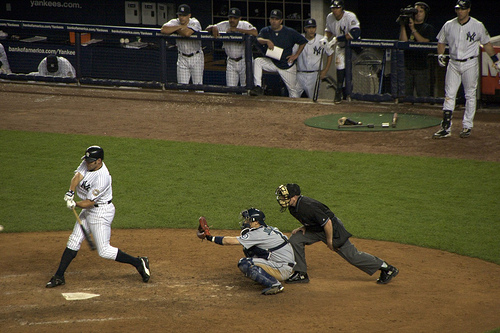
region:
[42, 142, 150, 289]
Baseball batter swinging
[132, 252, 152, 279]
Black and white shoe on baseball batter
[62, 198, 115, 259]
White pants with pinstripes on baseball batter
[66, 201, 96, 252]
Brown and black bat held by baseball batter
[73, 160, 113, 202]
White jersey with pinstripes on baseball batter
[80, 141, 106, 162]
Black helmet on baseball batter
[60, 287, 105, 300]
White home plate on a baseball field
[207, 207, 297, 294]
Catcher in squat in baseball game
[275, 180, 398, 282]
Home plate umpire in dark clothing in baseball game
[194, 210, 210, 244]
Brown mitt on baseball catcher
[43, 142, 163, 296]
Baseball batter swinging at a pitch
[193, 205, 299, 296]
Baseball catcher about to catch a pitch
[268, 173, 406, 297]
Baseball umpire alert and ready to make a call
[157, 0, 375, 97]
Baseball players in the dugout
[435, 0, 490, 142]
Baseball batter on deck about to hit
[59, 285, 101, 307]
Home plate of a baseball game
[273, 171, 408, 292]
Home plate umpire of a baseball game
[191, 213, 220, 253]
Baseball catching glove being worn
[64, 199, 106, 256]
Baseball bat mid swing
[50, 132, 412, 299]
Baseball hitter, catcher, and umpire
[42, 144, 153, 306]
Batter at home plate.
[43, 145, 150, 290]
Baseball player swinging a bat.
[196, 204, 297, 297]
Catcher crouching to catch the ball.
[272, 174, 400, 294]
Umpire dressed mainly in black.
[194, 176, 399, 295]
Catcher with umpire standing behind him.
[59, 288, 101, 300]
Home plate.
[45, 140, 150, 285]
Player up at bat.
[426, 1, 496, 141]
Player on deck.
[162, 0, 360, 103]
Team waiting in the dugout.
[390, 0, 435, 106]
Cameraman filming the game.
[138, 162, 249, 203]
green artificial turf on field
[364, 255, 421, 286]
black top sneakers with white spot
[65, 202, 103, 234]
wooden bat in player's hand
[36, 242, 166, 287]
pair of tall black socks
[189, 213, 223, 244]
brown glove in catcher's hand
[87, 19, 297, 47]
black railing in the bull pen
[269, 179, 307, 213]
brown and gold face mask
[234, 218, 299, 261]
strap around catcher's waist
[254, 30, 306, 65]
white paper in man's hand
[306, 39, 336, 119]
shiny black baseball bat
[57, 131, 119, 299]
base ball player wearing uniform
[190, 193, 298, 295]
base ball player wearing uniform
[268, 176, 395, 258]
base ball player wearing uniform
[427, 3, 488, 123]
base ball player wearing uniform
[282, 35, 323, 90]
base ball player wearing uniform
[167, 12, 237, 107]
base ball player wearing uniform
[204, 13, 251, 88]
base ball player wearing uniform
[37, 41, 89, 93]
base ball player wearing uniform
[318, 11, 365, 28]
base ball player wearing uniform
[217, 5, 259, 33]
base ball player wearing uniform